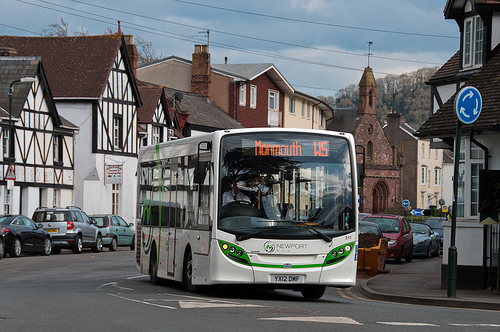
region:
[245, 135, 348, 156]
orange words on bus front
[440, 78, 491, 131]
large blue sign with circular lines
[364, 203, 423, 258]
small passenger red car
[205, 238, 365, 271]
green lines on the passenger bus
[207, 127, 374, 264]
large glass area in bus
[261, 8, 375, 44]
blue clouds in sky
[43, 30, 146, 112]
dark brown roof on house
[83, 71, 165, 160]
black and white design on house's front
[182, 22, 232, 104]
brown chimney on roof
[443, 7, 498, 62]
white windows in building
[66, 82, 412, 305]
bus traveling through a quaint village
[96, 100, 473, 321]
bus making a turn at a corner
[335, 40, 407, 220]
brick building with steeple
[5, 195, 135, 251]
cars parked along the curb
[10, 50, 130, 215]
white building with dark wood trim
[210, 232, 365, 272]
headlights in green oval panels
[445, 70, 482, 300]
blue and white traffic sign with arrows in a circle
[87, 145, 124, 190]
elevated sign hanging by door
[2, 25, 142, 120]
pitched roofs in different coverings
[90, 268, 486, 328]
white markings on street in different shapes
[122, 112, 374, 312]
bus on a street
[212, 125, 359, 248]
front windshield of a bus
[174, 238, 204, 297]
wheel on a vehicle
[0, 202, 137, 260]
cars parked on a street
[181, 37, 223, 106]
chimney on a building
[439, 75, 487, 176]
blue and white sign on a pole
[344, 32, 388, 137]
steeple on a building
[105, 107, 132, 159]
window on a building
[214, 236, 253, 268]
front headlight on a vehicle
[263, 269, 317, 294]
front licence plate on a vehicle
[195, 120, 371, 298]
A bus.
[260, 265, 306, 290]
The bus' license plate.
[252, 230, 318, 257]
The name of the bus company.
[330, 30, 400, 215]
A church in the background.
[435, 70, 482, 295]
A street sign.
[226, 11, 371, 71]
The sky is overcast.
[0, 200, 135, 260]
Cars parked on the side of the road.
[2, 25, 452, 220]
A row of buildings side by side.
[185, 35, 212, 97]
A chimney made from bricks.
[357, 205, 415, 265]
A red car.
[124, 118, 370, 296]
A COMMUTER BUS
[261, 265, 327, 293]
A FRONT BUS LICENSE PLATE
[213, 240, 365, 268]
A PAIR OF BUS HEADLIGHTS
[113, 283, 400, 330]
WHITE PAVEMENT MARKINGS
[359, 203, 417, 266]
A RED CAR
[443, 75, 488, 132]
A BLUE STREET SIGN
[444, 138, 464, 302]
A GREEN METAL POLE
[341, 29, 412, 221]
A CHURCH IN THE BACKGROUND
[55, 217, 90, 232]
A REAR HEADLIGHT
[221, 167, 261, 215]
A BUS DRIVER BEHIND THE WHEEL